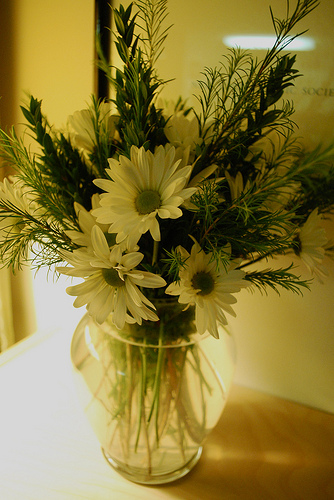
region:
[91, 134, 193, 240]
white flower in vase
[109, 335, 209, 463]
stems inside glass vase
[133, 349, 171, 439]
green stems inside vase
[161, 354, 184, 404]
brown stems inside vase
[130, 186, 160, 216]
grey middle of flower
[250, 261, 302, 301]
green leaves on plants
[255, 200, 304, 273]
long green stem of flower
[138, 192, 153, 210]
green and brown middle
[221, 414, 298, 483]
wooden table beneath vase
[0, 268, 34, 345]
white curtain in back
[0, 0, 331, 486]
Vase of flowers on table.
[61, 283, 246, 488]
Clear vase on the table.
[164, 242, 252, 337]
White flower in the vase.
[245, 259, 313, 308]
Green plant in the vase.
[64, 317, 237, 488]
Water in the vase.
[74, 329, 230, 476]
Stems in the vase.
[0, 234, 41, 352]
Drapes in the background.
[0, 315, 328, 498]
Wood table in the forefront.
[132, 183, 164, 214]
Florets of the flower.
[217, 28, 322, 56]
Reflection of a light.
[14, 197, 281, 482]
the vase is on the table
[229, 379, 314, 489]
the table is tan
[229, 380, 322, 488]
the table is made of wood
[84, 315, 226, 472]
the stems are in the vase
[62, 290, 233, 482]
the vase has water in it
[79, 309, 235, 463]
the stems are in the water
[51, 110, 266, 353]
the flowers are white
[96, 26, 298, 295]
the leaves are green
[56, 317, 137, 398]
the light is reflecting on the vase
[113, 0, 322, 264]
a picture behind the flowers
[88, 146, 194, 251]
the flower is white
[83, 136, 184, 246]
the flower is white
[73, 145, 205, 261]
the flower is white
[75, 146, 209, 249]
the flower is white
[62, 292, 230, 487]
the vase has water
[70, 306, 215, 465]
the vase has water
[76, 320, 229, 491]
the vase has water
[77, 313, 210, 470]
the vase has water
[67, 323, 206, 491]
the vase has water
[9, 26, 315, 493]
Flowers in a vase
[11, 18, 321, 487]
Flowers in a vase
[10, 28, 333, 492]
Flowers in a vase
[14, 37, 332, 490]
Flowers in a vase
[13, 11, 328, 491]
Flowers in a vase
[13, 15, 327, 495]
Flowers in a vase